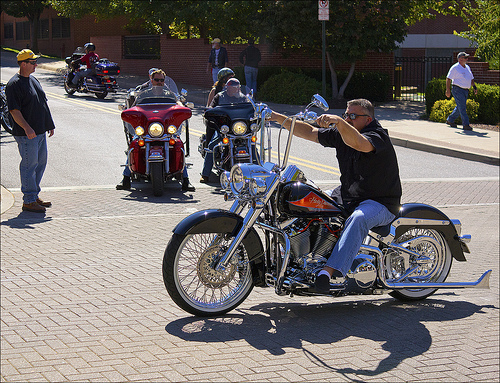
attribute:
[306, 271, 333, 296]
shoes — white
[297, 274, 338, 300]
shoes — black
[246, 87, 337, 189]
handles — chrome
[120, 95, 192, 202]
motorcycle — red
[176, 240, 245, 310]
rim — chrome